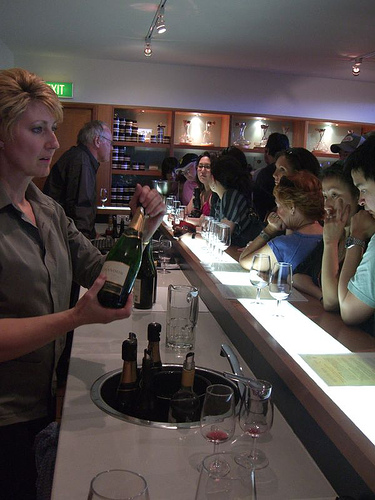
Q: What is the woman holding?
A: A wine bottle.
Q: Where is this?
A: Bar.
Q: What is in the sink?
A: Bottles.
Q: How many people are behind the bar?
A: 2.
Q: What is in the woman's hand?
A: Wine.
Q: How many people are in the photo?
A: 13.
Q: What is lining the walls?
A: Shelves.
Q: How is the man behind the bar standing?
A: Leaning.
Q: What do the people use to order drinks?
A: Menu.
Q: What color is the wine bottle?
A: Green and gold.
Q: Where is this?
A: Bar.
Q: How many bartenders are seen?
A: 2.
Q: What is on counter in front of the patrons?
A: Wine glasses.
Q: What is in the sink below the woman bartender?
A: Wine bottles.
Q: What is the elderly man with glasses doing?
A: Taking drink orders.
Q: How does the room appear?
A: Dimly lit and crowded.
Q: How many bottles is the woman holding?
A: 1.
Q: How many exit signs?
A: 1.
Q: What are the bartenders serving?
A: Drinks.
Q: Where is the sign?
A: Over the door.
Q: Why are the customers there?
A: To drink.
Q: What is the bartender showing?
A: Bottle.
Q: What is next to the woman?
A: The man.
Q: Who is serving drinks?
A: Man and woman.